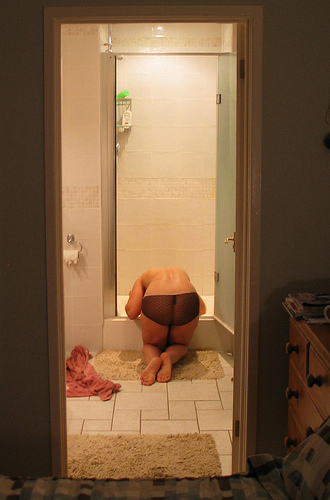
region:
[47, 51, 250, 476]
Woman viewed through opened bathroom door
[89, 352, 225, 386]
Bare feet on brown bath rug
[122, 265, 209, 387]
Woman kneeling into opened shower stall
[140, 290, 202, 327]
Woman in brown panties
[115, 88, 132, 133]
Shower caddy with products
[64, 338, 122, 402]
Rumpled red towel on bathroom floor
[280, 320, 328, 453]
Brown wooden dresser drawers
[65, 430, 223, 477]
Tan bathroom rug on floor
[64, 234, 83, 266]
Toilet tissue on dispenser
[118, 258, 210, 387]
Partially clad women kneeling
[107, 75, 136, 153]
there is a rack in the shower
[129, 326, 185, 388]
the ladies feet are together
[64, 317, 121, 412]
there is a towel in the floor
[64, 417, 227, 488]
a beige rug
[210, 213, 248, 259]
the knob on the door is gold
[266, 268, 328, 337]
there is a stack of books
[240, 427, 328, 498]
the woman's pillow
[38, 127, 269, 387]
an unusual scene of a person throwing up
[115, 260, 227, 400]
this person is bent over a tub for some reason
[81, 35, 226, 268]
this is a shower area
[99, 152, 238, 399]
this picture shows someone being sick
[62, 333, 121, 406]
a pink garment on the ground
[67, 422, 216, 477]
a tan throw rug on the floor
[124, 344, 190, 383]
this person is barefoot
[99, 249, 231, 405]
this is a woman bent over a tub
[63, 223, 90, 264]
a toilet paper roll on the wall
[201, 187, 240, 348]
a shower door in the bathroom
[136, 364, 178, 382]
these are some feet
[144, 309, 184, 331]
this is some underwear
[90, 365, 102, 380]
this is a towel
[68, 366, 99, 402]
the towel is red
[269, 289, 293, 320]
these are some magazines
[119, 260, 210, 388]
Lady in black panties bending over shower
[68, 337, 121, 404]
pink towel on tile floor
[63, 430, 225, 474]
beige rug on tile floor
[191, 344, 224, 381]
beige rug on tile floor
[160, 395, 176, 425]
grout lines on tile floor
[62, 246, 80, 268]
toilet paper on toilet paper hanger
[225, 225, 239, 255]
gold door knob on door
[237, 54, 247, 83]
brass hinge on door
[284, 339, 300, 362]
wood pull knob on dresser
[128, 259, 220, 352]
a person wearing underwear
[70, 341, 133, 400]
a towel on the floor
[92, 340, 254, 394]
a rug on the floor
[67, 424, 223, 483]
a rug on the floor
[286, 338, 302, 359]
a brown drawer knob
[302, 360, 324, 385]
a brown drawer knob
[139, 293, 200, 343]
the underwear is see thru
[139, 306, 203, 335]
the underwear is brown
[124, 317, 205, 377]
the legs are bare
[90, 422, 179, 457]
the bath rug is shaggy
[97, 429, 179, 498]
the bath rug is tan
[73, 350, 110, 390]
the towels are orange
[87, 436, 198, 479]
a rug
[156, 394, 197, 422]
the tile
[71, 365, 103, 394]
a red towel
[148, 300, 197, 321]
a persons underwear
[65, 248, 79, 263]
toilet tissue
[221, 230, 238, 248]
a door handle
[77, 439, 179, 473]
the rug is brown